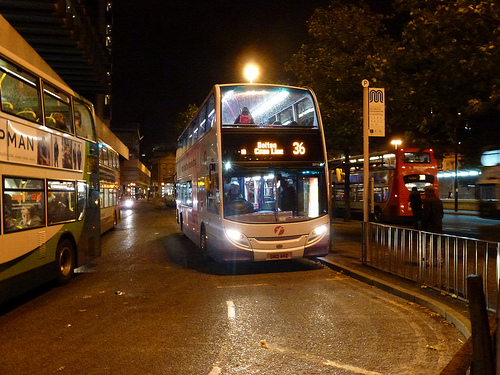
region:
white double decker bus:
[172, 80, 332, 265]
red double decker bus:
[326, 145, 438, 224]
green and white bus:
[0, 44, 104, 309]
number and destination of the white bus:
[222, 135, 320, 162]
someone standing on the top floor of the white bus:
[233, 105, 256, 127]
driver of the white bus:
[222, 179, 252, 214]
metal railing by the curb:
[358, 218, 498, 315]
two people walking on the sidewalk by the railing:
[407, 183, 446, 269]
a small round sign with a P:
[356, 75, 371, 89]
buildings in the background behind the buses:
[108, 115, 178, 203]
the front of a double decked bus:
[208, 78, 333, 265]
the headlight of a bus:
[217, 222, 242, 242]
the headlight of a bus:
[310, 221, 330, 236]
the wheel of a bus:
[52, 235, 77, 287]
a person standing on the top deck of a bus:
[228, 102, 260, 130]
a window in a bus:
[37, 70, 74, 135]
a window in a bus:
[42, 172, 74, 224]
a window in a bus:
[0, 170, 46, 235]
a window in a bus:
[0, 50, 42, 125]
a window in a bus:
[71, 94, 98, 146]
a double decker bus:
[153, 70, 343, 283]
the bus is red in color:
[339, 148, 444, 225]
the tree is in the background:
[307, 9, 491, 171]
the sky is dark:
[125, 11, 463, 108]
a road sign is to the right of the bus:
[358, 75, 394, 267]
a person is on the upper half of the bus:
[235, 105, 255, 126]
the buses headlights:
[206, 209, 332, 256]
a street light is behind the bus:
[233, 43, 274, 84]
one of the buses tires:
[55, 230, 83, 284]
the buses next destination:
[231, 133, 318, 156]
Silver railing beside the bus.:
[348, 223, 496, 292]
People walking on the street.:
[402, 178, 453, 235]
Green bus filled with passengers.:
[5, 75, 93, 250]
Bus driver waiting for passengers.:
[223, 171, 253, 229]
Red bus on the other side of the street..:
[330, 133, 443, 218]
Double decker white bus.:
[205, 53, 339, 271]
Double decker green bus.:
[0, 53, 108, 296]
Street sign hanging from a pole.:
[351, 77, 396, 264]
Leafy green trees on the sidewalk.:
[329, 33, 485, 131]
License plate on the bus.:
[261, 243, 298, 269]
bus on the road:
[134, 46, 449, 373]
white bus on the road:
[139, 60, 401, 329]